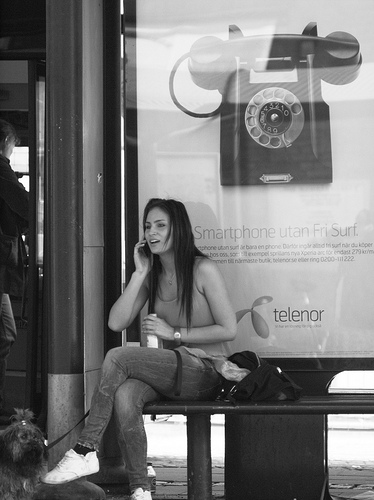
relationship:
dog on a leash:
[0, 407, 50, 499] [44, 348, 182, 449]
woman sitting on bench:
[40, 198, 236, 499] [142, 392, 373, 499]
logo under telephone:
[233, 296, 273, 341] [168, 21, 362, 186]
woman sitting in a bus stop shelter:
[40, 198, 236, 499] [0, 0, 373, 499]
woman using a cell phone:
[40, 198, 236, 499] [140, 237, 150, 260]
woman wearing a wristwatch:
[40, 198, 236, 499] [172, 325, 181, 347]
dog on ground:
[0, 407, 50, 499] [0, 415, 373, 499]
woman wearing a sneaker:
[40, 198, 236, 499] [40, 445, 100, 485]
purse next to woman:
[217, 351, 303, 404] [40, 198, 236, 499]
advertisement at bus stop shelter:
[124, 1, 373, 371] [0, 0, 373, 499]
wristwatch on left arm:
[172, 325, 181, 347] [142, 256, 237, 343]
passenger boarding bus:
[1, 120, 30, 418] [1, 0, 173, 429]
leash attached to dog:
[44, 348, 182, 449] [0, 407, 50, 499]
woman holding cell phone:
[40, 198, 236, 499] [140, 237, 150, 260]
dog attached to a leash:
[0, 407, 50, 499] [44, 348, 182, 449]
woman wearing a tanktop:
[40, 198, 236, 499] [151, 257, 226, 358]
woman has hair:
[40, 198, 236, 499] [144, 198, 212, 334]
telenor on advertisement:
[272, 306, 324, 322] [124, 1, 373, 371]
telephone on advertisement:
[168, 21, 362, 186] [124, 1, 373, 371]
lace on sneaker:
[55, 452, 73, 472] [40, 445, 100, 485]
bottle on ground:
[146, 461, 156, 493] [0, 415, 373, 499]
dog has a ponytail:
[0, 407, 50, 499] [9, 406, 36, 426]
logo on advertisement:
[233, 296, 273, 341] [124, 1, 373, 371]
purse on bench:
[217, 351, 303, 404] [142, 392, 373, 499]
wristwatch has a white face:
[172, 325, 181, 347] [173, 332, 181, 339]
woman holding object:
[40, 198, 236, 499] [146, 313, 159, 348]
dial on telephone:
[244, 87, 304, 149] [168, 21, 362, 186]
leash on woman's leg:
[44, 348, 182, 449] [43, 346, 223, 484]